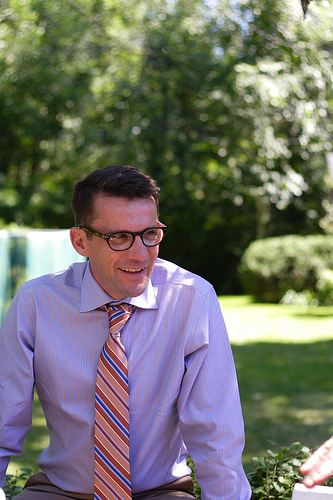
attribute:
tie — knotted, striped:
[88, 300, 142, 499]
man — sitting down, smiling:
[4, 140, 267, 497]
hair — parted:
[66, 154, 165, 225]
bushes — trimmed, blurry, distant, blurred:
[234, 225, 332, 300]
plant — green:
[247, 435, 331, 499]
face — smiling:
[98, 206, 163, 295]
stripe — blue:
[98, 348, 129, 386]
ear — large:
[67, 225, 93, 258]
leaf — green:
[200, 24, 207, 44]